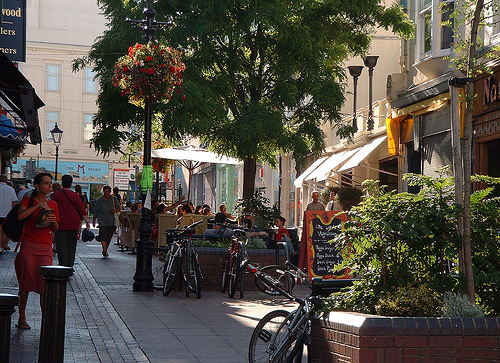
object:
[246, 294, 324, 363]
bicycle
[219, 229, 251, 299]
bicycle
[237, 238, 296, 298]
bicycle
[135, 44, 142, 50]
flower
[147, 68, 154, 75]
flower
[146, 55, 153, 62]
flower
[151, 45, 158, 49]
flower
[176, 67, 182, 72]
flower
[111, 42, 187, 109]
plant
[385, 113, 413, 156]
flag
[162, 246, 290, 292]
planters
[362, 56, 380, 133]
sconces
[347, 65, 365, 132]
sconces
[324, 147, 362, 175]
awnings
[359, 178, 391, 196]
leaves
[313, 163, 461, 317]
plant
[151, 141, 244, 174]
white umbrella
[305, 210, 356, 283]
poster board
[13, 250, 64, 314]
woman walking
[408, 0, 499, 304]
tree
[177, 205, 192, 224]
woman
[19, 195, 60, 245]
red shirt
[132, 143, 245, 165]
umbrella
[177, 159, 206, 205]
pole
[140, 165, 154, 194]
poster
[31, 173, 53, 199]
woman's hair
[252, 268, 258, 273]
bikereflector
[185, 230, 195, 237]
bikereflector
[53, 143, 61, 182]
pole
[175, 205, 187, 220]
woman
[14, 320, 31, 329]
foot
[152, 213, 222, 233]
tables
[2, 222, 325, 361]
sidewalk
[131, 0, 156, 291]
pole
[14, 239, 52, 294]
skirt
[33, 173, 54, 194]
head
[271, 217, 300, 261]
people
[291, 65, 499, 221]
shops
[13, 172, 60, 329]
woman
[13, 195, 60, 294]
dress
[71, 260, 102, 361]
walkway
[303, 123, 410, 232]
store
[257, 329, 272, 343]
pedal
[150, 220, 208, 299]
bike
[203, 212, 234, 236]
people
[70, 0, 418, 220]
tree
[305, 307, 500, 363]
planter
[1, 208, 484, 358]
area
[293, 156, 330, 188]
awning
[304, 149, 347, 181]
awning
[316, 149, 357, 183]
awning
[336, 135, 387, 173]
awning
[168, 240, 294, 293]
step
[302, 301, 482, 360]
step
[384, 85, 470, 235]
store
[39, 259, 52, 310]
leg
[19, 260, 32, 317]
leg